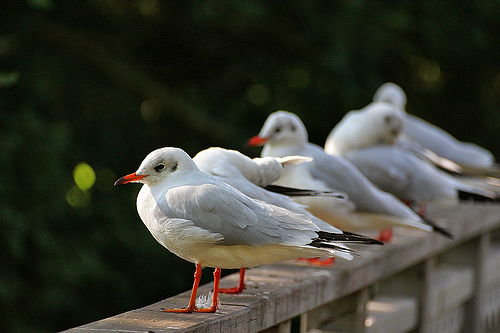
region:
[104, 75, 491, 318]
five sea birds over a surface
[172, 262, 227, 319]
red legs of bird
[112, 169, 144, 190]
red and black peak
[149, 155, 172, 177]
eye of bird is black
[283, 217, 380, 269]
black feathers on tail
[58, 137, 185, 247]
a green light on face of bird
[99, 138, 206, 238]
bird face the left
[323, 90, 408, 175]
head of bird is flipped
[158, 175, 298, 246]
wing of bird is gray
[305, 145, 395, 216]
wing of bird is gray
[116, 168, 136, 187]
Bird has black and orange beak.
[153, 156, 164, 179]
Bird has dark eyel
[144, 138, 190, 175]
Bird has white head.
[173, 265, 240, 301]
Bird has orange legs.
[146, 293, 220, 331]
Bird has orange feet.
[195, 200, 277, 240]
Bird has gray wing.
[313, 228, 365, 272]
Bird has black tail feathers.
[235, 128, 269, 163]
Bird has orange beak.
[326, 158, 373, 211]
Bird has gray wing.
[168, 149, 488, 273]
Birds standing on wood ledge.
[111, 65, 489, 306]
several birds perched on a railing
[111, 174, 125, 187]
black tip on the beak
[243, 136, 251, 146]
black tip on the beak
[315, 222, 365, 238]
black tail feathers on the bird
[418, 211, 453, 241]
black tail feathers on the bird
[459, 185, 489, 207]
black tail feathers on the bird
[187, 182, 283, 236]
gray wing feathers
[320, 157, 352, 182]
gray wing feathers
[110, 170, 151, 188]
orange and black beak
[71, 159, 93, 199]
a green light in the foreground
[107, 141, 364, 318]
sunning birds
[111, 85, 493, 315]
seagulls resting on a rail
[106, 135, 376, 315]
Seagull looking for food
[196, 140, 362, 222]
seagull bathing itself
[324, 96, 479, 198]
seagull grooming itself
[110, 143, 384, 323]
Seagull resting with friends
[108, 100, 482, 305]
resting for their next flight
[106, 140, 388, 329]
looking for their next meal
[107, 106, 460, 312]
seagulls resting on a wooden ledge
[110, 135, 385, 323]
getting ready to look for food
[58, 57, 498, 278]
five birds on a ledge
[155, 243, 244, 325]
dark orange legs on bird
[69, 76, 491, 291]
five white and gray birds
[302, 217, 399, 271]
a few black tail feathers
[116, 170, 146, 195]
orange beak on bird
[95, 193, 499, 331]
a wooden ledge with birds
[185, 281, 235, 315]
a feather by the bird's food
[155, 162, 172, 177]
black eye of a bird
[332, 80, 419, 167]
one bird has head on back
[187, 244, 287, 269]
white underbelly of bird